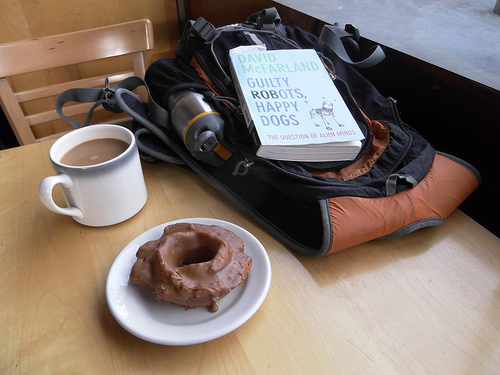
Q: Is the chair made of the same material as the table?
A: Yes, both the chair and the table are made of wood.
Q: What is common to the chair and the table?
A: The material, both the chair and the table are wooden.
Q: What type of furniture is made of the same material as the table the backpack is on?
A: The chair is made of the same material as the table.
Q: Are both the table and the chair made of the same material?
A: Yes, both the table and the chair are made of wood.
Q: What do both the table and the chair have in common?
A: The material, both the table and the chair are wooden.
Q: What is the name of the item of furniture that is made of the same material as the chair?
A: The piece of furniture is a table.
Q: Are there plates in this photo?
A: Yes, there is a plate.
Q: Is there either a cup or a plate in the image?
A: Yes, there is a plate.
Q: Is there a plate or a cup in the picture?
A: Yes, there is a plate.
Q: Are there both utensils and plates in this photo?
A: No, there is a plate but no utensils.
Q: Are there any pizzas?
A: No, there are no pizzas.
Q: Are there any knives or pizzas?
A: No, there are no pizzas or knives.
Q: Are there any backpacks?
A: Yes, there is a backpack.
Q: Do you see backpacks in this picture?
A: Yes, there is a backpack.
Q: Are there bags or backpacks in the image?
A: Yes, there is a backpack.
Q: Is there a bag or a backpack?
A: Yes, there is a backpack.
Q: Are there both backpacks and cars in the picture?
A: No, there is a backpack but no cars.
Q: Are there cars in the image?
A: No, there are no cars.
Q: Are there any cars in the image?
A: No, there are no cars.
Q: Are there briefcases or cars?
A: No, there are no cars or briefcases.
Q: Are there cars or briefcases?
A: No, there are no cars or briefcases.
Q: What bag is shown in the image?
A: The bag is a backpack.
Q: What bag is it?
A: The bag is a backpack.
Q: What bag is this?
A: This is a backpack.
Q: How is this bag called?
A: This is a backpack.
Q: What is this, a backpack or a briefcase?
A: This is a backpack.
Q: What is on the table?
A: The backpack is on the table.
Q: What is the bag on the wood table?
A: The bag is a backpack.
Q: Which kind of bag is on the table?
A: The bag is a backpack.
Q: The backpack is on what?
A: The backpack is on the table.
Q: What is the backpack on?
A: The backpack is on the table.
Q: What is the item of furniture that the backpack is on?
A: The piece of furniture is a table.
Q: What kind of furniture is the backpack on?
A: The backpack is on the table.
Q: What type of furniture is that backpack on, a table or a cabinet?
A: The backpack is on a table.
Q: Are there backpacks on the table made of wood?
A: Yes, there is a backpack on the table.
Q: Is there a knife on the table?
A: No, there is a backpack on the table.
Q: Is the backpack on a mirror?
A: No, the backpack is on a table.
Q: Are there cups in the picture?
A: Yes, there is a cup.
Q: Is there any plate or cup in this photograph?
A: Yes, there is a cup.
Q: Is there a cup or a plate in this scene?
A: Yes, there is a cup.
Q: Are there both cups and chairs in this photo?
A: Yes, there are both a cup and a chair.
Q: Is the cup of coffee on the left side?
A: Yes, the cup is on the left of the image.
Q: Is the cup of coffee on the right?
A: No, the cup is on the left of the image.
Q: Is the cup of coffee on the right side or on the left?
A: The cup is on the left of the image.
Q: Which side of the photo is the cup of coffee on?
A: The cup is on the left of the image.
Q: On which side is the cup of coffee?
A: The cup is on the left of the image.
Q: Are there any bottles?
A: Yes, there is a bottle.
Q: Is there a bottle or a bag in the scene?
A: Yes, there is a bottle.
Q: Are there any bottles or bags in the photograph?
A: Yes, there is a bottle.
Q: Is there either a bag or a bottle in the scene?
A: Yes, there is a bottle.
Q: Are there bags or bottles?
A: Yes, there is a bottle.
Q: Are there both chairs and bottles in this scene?
A: Yes, there are both a bottle and a chair.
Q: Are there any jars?
A: No, there are no jars.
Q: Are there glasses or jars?
A: No, there are no jars or glasses.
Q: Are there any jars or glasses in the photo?
A: No, there are no jars or glasses.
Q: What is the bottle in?
A: The bottle is in the backpack.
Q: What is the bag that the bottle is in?
A: The bag is a backpack.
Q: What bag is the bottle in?
A: The bottle is in the backpack.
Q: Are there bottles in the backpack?
A: Yes, there is a bottle in the backpack.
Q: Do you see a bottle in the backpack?
A: Yes, there is a bottle in the backpack.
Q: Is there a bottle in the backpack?
A: Yes, there is a bottle in the backpack.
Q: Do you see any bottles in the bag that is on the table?
A: Yes, there is a bottle in the backpack.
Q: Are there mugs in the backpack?
A: No, there is a bottle in the backpack.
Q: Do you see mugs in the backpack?
A: No, there is a bottle in the backpack.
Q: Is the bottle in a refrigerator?
A: No, the bottle is in the backpack.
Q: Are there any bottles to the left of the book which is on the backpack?
A: Yes, there is a bottle to the left of the book.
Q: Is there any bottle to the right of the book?
A: No, the bottle is to the left of the book.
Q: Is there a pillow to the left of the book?
A: No, there is a bottle to the left of the book.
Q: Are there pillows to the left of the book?
A: No, there is a bottle to the left of the book.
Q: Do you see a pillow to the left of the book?
A: No, there is a bottle to the left of the book.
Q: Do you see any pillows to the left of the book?
A: No, there is a bottle to the left of the book.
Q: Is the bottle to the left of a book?
A: Yes, the bottle is to the left of a book.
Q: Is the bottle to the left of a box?
A: No, the bottle is to the left of a book.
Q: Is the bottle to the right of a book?
A: No, the bottle is to the left of a book.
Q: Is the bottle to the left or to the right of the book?
A: The bottle is to the left of the book.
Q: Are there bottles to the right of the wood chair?
A: Yes, there is a bottle to the right of the chair.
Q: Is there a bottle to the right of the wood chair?
A: Yes, there is a bottle to the right of the chair.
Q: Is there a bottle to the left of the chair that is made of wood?
A: No, the bottle is to the right of the chair.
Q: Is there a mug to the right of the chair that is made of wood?
A: No, there is a bottle to the right of the chair.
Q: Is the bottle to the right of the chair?
A: Yes, the bottle is to the right of the chair.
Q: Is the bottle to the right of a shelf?
A: No, the bottle is to the right of the chair.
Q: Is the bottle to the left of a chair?
A: No, the bottle is to the right of a chair.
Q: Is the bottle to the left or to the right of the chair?
A: The bottle is to the right of the chair.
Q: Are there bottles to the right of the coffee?
A: Yes, there is a bottle to the right of the coffee.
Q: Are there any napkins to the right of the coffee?
A: No, there is a bottle to the right of the coffee.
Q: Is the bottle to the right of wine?
A: No, the bottle is to the right of the coffee.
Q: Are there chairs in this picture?
A: Yes, there is a chair.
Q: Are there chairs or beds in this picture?
A: Yes, there is a chair.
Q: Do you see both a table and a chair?
A: Yes, there are both a chair and a table.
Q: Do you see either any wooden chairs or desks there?
A: Yes, there is a wood chair.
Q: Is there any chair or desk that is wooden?
A: Yes, the chair is wooden.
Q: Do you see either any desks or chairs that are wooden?
A: Yes, the chair is wooden.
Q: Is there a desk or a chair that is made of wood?
A: Yes, the chair is made of wood.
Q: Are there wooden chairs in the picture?
A: Yes, there is a wood chair.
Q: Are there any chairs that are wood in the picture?
A: Yes, there is a wood chair.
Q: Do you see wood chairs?
A: Yes, there is a wood chair.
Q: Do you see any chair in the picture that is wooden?
A: Yes, there is a chair that is wooden.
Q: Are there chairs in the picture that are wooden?
A: Yes, there is a chair that is wooden.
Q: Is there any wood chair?
A: Yes, there is a chair that is made of wood.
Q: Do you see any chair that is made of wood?
A: Yes, there is a chair that is made of wood.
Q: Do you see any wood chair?
A: Yes, there is a chair that is made of wood.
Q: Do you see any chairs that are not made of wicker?
A: Yes, there is a chair that is made of wood.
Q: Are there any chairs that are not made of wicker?
A: Yes, there is a chair that is made of wood.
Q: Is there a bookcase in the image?
A: No, there are no bookcases.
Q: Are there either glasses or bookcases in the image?
A: No, there are no bookcases or glasses.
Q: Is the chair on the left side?
A: Yes, the chair is on the left of the image.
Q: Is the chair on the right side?
A: No, the chair is on the left of the image.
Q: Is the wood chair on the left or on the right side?
A: The chair is on the left of the image.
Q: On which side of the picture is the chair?
A: The chair is on the left of the image.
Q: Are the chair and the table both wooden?
A: Yes, both the chair and the table are wooden.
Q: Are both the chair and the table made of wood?
A: Yes, both the chair and the table are made of wood.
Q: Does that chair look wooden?
A: Yes, the chair is wooden.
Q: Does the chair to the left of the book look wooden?
A: Yes, the chair is wooden.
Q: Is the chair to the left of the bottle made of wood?
A: Yes, the chair is made of wood.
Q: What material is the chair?
A: The chair is made of wood.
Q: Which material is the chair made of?
A: The chair is made of wood.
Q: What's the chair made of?
A: The chair is made of wood.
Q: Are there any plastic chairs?
A: No, there is a chair but it is made of wood.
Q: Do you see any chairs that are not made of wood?
A: No, there is a chair but it is made of wood.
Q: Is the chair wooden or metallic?
A: The chair is wooden.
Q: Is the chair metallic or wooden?
A: The chair is wooden.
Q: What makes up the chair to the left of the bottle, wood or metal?
A: The chair is made of wood.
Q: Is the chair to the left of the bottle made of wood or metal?
A: The chair is made of wood.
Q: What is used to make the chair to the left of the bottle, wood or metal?
A: The chair is made of wood.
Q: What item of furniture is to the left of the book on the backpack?
A: The piece of furniture is a chair.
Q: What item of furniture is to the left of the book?
A: The piece of furniture is a chair.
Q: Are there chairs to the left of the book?
A: Yes, there is a chair to the left of the book.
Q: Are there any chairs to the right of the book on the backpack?
A: No, the chair is to the left of the book.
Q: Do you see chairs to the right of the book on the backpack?
A: No, the chair is to the left of the book.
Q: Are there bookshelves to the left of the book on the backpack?
A: No, there is a chair to the left of the book.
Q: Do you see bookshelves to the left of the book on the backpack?
A: No, there is a chair to the left of the book.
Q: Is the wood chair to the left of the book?
A: Yes, the chair is to the left of the book.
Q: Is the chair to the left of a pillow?
A: No, the chair is to the left of the book.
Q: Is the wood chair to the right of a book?
A: No, the chair is to the left of a book.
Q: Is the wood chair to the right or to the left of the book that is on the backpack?
A: The chair is to the left of the book.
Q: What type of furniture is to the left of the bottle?
A: The piece of furniture is a chair.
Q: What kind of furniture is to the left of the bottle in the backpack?
A: The piece of furniture is a chair.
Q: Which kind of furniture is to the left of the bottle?
A: The piece of furniture is a chair.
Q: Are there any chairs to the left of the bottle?
A: Yes, there is a chair to the left of the bottle.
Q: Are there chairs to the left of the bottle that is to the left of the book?
A: Yes, there is a chair to the left of the bottle.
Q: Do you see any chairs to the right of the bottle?
A: No, the chair is to the left of the bottle.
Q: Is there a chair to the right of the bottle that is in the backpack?
A: No, the chair is to the left of the bottle.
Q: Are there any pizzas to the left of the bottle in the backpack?
A: No, there is a chair to the left of the bottle.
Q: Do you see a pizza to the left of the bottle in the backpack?
A: No, there is a chair to the left of the bottle.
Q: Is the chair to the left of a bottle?
A: Yes, the chair is to the left of a bottle.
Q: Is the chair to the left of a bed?
A: No, the chair is to the left of a bottle.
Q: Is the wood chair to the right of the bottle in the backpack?
A: No, the chair is to the left of the bottle.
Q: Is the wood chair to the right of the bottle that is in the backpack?
A: No, the chair is to the left of the bottle.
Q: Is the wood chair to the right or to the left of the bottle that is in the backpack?
A: The chair is to the left of the bottle.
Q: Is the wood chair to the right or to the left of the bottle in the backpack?
A: The chair is to the left of the bottle.